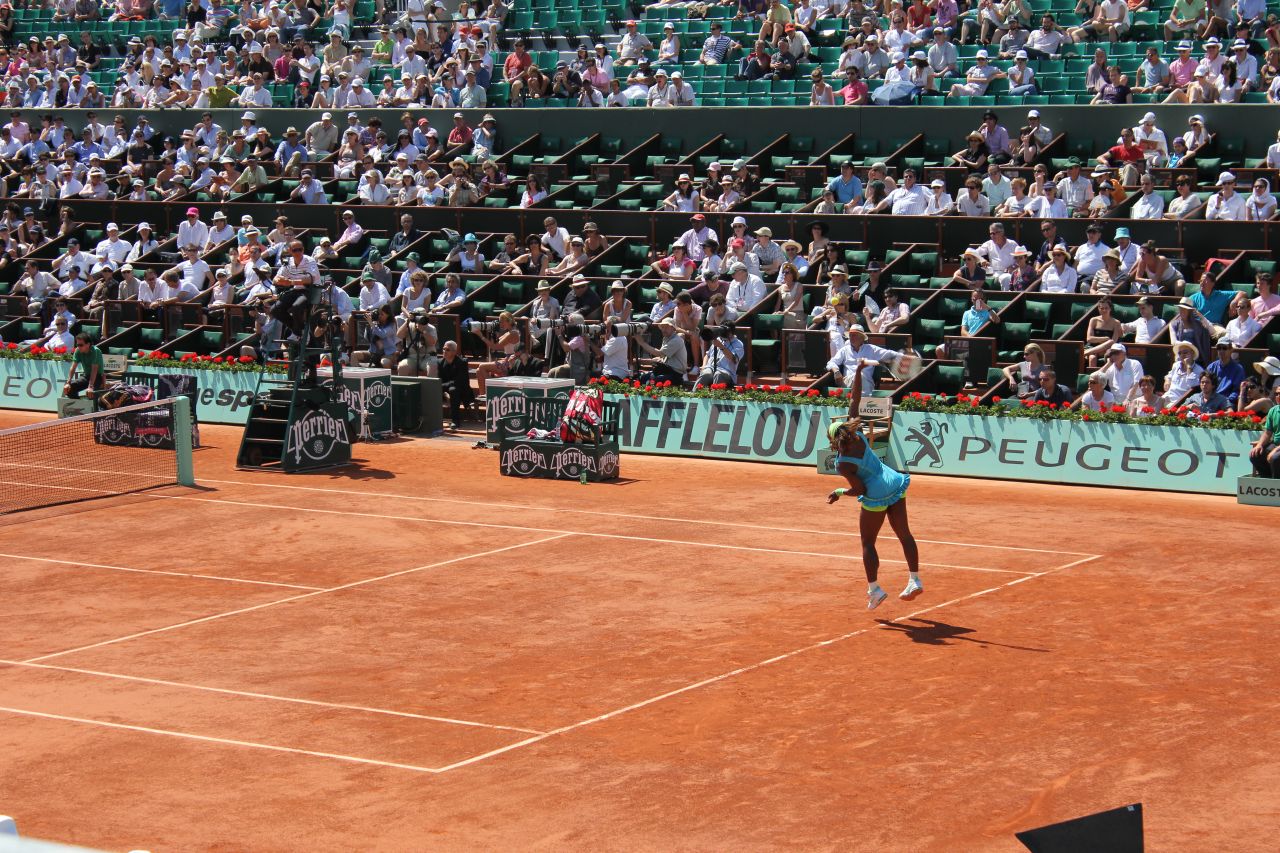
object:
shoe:
[867, 587, 887, 610]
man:
[724, 260, 759, 319]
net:
[0, 390, 196, 520]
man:
[826, 359, 924, 612]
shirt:
[357, 182, 396, 205]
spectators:
[0, 0, 1278, 417]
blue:
[830, 437, 908, 506]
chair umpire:
[252, 236, 327, 320]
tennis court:
[6, 385, 1280, 850]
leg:
[851, 504, 888, 610]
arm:
[828, 461, 865, 503]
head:
[826, 420, 858, 453]